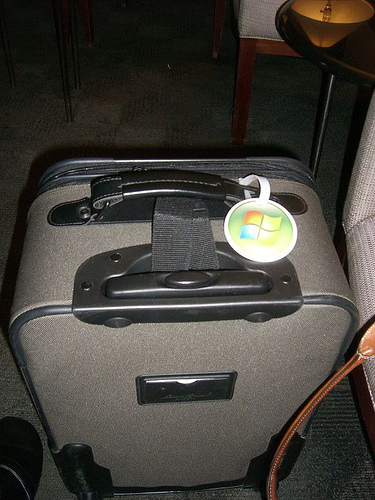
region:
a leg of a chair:
[231, 46, 259, 141]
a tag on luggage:
[223, 168, 301, 261]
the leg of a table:
[303, 72, 338, 170]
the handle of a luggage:
[86, 162, 201, 216]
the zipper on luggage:
[58, 164, 122, 175]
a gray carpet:
[88, 72, 182, 138]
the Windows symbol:
[232, 206, 287, 255]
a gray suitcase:
[23, 156, 355, 335]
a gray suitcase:
[4, 306, 347, 476]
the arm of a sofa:
[347, 140, 373, 233]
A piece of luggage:
[13, 148, 373, 489]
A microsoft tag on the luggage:
[229, 168, 291, 271]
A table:
[278, 0, 374, 183]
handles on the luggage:
[87, 176, 282, 315]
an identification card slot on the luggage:
[133, 368, 243, 417]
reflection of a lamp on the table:
[297, 0, 365, 62]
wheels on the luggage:
[53, 460, 294, 498]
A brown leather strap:
[250, 332, 371, 498]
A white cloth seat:
[330, 96, 374, 467]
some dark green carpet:
[0, 5, 363, 489]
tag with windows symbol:
[222, 175, 297, 261]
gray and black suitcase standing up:
[9, 155, 362, 493]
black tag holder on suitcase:
[132, 371, 235, 405]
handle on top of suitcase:
[46, 172, 309, 227]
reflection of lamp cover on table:
[287, 0, 371, 50]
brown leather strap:
[262, 317, 373, 498]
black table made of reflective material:
[271, 0, 370, 181]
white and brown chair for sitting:
[228, 0, 307, 143]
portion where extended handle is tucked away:
[69, 240, 303, 325]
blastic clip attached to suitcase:
[236, 172, 270, 202]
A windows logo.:
[225, 168, 301, 264]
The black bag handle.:
[78, 159, 234, 210]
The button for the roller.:
[158, 266, 218, 294]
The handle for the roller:
[105, 269, 272, 310]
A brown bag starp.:
[265, 334, 373, 497]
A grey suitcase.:
[2, 122, 372, 498]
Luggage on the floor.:
[8, 141, 373, 497]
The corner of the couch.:
[337, 70, 374, 304]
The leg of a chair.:
[227, 37, 257, 153]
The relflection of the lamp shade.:
[284, 0, 374, 54]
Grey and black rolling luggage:
[16, 155, 312, 497]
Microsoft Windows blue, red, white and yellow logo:
[234, 207, 282, 242]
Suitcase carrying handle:
[55, 170, 306, 220]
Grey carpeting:
[305, 420, 365, 498]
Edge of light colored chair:
[340, 134, 374, 279]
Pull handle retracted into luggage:
[73, 250, 296, 330]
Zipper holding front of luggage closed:
[54, 161, 299, 177]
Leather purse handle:
[260, 325, 373, 494]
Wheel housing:
[49, 446, 110, 499]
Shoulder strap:
[147, 196, 227, 266]